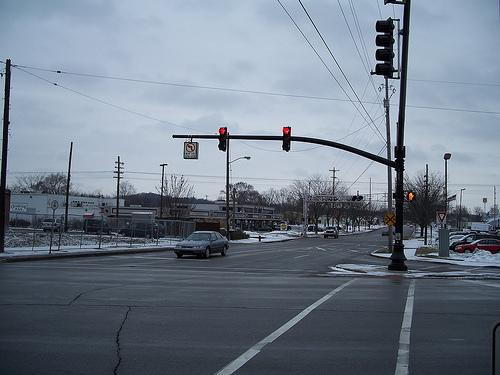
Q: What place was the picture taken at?
A: It was taken at the road.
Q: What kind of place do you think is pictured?
A: It is a road.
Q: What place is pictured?
A: It is a road.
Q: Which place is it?
A: It is a road.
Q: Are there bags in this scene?
A: No, there are no bags.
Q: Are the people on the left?
A: Yes, the people are on the left of the image.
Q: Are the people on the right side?
A: No, the people are on the left of the image.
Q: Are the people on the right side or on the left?
A: The people are on the left of the image.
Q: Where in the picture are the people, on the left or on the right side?
A: The people are on the left of the image.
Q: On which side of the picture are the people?
A: The people are on the left of the image.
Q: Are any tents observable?
A: No, there are no tents.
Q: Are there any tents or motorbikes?
A: No, there are no tents or motorbikes.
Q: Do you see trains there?
A: No, there are no trains.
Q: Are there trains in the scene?
A: No, there are no trains.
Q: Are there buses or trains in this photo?
A: No, there are no trains or buses.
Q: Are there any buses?
A: No, there are no buses.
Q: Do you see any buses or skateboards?
A: No, there are no buses or skateboards.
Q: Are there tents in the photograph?
A: No, there are no tents.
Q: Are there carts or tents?
A: No, there are no tents or carts.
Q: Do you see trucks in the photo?
A: No, there are no trucks.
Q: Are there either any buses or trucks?
A: No, there are no trucks or buses.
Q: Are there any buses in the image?
A: No, there are no buses.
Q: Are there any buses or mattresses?
A: No, there are no buses or mattresses.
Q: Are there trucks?
A: No, there are no trucks.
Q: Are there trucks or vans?
A: No, there are no trucks or vans.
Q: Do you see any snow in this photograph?
A: Yes, there is snow.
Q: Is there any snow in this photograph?
A: Yes, there is snow.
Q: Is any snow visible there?
A: Yes, there is snow.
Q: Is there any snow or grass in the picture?
A: Yes, there is snow.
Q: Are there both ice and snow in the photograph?
A: No, there is snow but no ice.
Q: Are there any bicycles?
A: No, there are no bicycles.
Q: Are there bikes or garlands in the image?
A: No, there are no bikes or garlands.